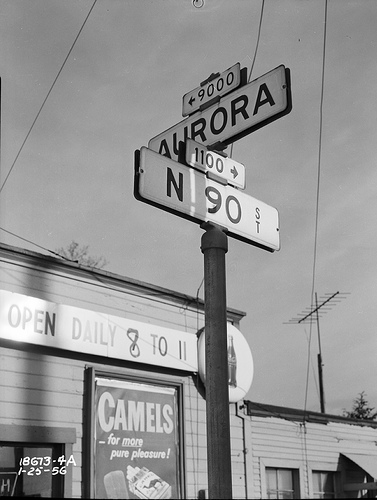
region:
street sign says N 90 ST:
[158, 160, 249, 235]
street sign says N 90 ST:
[129, 144, 325, 257]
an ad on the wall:
[74, 371, 192, 497]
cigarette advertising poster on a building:
[88, 370, 184, 498]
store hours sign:
[1, 292, 197, 374]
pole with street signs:
[135, 61, 279, 499]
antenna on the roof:
[287, 283, 346, 415]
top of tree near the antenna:
[341, 392, 373, 419]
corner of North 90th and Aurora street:
[142, 63, 282, 252]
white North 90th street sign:
[137, 149, 278, 252]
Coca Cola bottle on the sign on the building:
[227, 336, 238, 386]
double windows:
[262, 458, 335, 497]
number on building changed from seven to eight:
[126, 327, 141, 356]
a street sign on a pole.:
[130, 142, 288, 258]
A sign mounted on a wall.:
[0, 288, 208, 378]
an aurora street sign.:
[145, 51, 301, 169]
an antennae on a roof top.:
[277, 278, 372, 413]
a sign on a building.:
[77, 357, 192, 499]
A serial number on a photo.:
[13, 439, 79, 486]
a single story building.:
[240, 398, 375, 496]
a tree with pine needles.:
[340, 383, 375, 423]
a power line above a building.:
[2, 2, 102, 189]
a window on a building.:
[252, 454, 309, 498]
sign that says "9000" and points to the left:
[178, 51, 238, 113]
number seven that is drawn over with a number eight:
[120, 315, 148, 366]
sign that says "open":
[4, 295, 61, 346]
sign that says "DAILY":
[63, 309, 121, 354]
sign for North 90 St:
[135, 155, 285, 245]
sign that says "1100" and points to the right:
[184, 139, 249, 183]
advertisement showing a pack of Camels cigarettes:
[124, 461, 177, 499]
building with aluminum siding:
[245, 397, 376, 497]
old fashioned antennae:
[279, 272, 374, 431]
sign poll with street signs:
[127, 32, 300, 499]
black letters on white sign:
[163, 165, 242, 224]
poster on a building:
[80, 363, 187, 498]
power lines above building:
[4, 0, 347, 420]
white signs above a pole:
[131, 66, 289, 254]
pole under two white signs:
[195, 221, 228, 498]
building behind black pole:
[2, 243, 374, 498]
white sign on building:
[0, 291, 200, 373]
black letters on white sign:
[4, 303, 192, 363]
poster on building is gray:
[88, 371, 190, 498]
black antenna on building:
[286, 289, 346, 414]